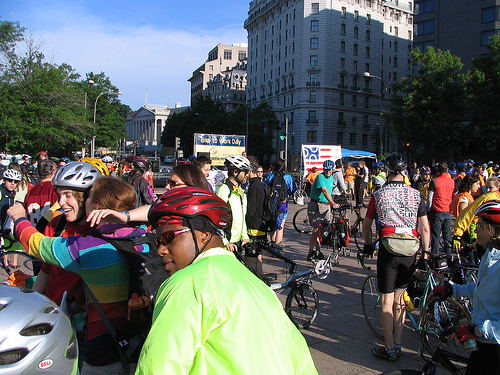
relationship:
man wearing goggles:
[139, 180, 296, 373] [145, 226, 202, 246]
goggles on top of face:
[145, 226, 202, 246] [150, 226, 190, 268]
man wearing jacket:
[139, 180, 296, 373] [155, 307, 298, 373]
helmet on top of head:
[40, 165, 96, 189] [53, 192, 85, 210]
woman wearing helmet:
[45, 149, 93, 227] [40, 165, 96, 189]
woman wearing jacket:
[45, 149, 93, 227] [70, 216, 128, 298]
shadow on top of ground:
[321, 306, 359, 354] [301, 274, 341, 293]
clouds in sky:
[85, 32, 167, 81] [115, 1, 200, 34]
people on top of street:
[213, 134, 452, 261] [262, 228, 354, 301]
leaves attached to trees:
[39, 139, 75, 153] [1, 80, 103, 147]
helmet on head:
[40, 165, 96, 189] [53, 192, 85, 210]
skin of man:
[384, 174, 408, 181] [139, 180, 296, 373]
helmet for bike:
[150, 188, 231, 229] [296, 203, 345, 236]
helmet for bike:
[382, 156, 408, 173] [296, 203, 345, 236]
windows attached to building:
[282, 21, 379, 70] [243, 0, 382, 139]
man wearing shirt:
[314, 159, 340, 203] [308, 178, 350, 203]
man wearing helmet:
[314, 159, 340, 203] [326, 160, 337, 170]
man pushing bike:
[314, 159, 340, 203] [296, 203, 345, 236]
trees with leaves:
[1, 80, 103, 147] [39, 139, 75, 153]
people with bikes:
[213, 134, 452, 261] [258, 195, 368, 315]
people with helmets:
[213, 134, 452, 261] [58, 160, 209, 220]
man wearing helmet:
[139, 180, 296, 373] [150, 188, 231, 229]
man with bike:
[139, 180, 296, 373] [296, 203, 345, 236]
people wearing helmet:
[213, 155, 253, 261] [225, 155, 253, 172]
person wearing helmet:
[0, 168, 46, 257] [3, 168, 22, 181]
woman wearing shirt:
[45, 149, 93, 227] [308, 178, 350, 203]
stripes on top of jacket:
[76, 261, 120, 296] [11, 218, 148, 345]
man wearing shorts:
[372, 146, 430, 325] [373, 247, 419, 291]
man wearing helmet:
[372, 146, 430, 325] [373, 154, 404, 169]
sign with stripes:
[303, 141, 337, 180] [76, 261, 120, 296]